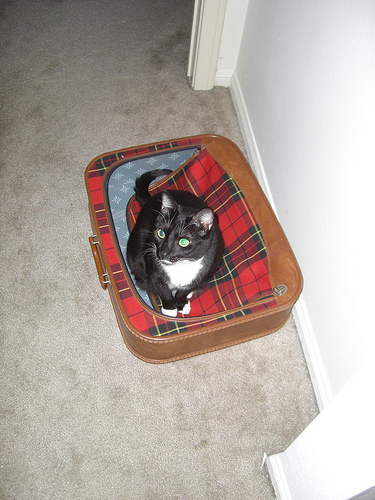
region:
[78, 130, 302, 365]
a black and white cat sitting in a suitcase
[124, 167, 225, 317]
a black and white cat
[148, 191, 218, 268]
the head of a cat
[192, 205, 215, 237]
the ear of a cat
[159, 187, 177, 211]
the ear of a cat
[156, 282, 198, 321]
the legs of a cat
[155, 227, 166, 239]
the eye of a cat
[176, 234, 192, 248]
the eye of a cat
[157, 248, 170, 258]
the nose of a cat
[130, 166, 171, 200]
the tail of a cat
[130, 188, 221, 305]
a cat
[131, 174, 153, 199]
the cats tail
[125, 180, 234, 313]
a black and white cat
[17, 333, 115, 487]
the carpet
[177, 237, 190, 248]
left eye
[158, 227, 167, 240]
right eye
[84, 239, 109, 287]
handle on the luggage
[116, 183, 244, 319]
the cat is sitting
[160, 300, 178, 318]
the cats paw is black and white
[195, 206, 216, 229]
the cats ear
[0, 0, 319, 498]
Brown carpeting on the floor.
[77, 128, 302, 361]
Luggage on the floor.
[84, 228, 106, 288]
Brown handle on the luggage.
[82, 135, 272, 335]
Plaid pattern on the luggage.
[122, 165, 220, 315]
Cat sitting in the luggage.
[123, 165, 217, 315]
black and white hair on the cat.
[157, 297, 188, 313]
White paws on the cat.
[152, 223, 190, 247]
Green eyes on the cat.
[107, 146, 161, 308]
blue color inside the luggage.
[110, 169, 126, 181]
White design in the luggage.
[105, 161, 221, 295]
cat inside a luggage piece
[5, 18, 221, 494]
carpet on the floor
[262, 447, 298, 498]
floorboard near corner of room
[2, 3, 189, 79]
doorway to the room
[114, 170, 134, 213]
inside of the luggage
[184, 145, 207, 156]
zipper to the luggage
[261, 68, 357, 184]
wall behind luggage piece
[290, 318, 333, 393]
floorboard near the wall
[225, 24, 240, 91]
corner of the room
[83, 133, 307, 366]
A cat inside of a suitcase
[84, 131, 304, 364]
a plaid suitcase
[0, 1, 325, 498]
grey carpet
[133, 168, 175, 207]
black cat tail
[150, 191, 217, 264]
black cat face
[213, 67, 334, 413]
white base board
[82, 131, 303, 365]
unzipped plaid suitcase with a cat in it.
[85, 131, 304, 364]
a plaid and leather suitcase